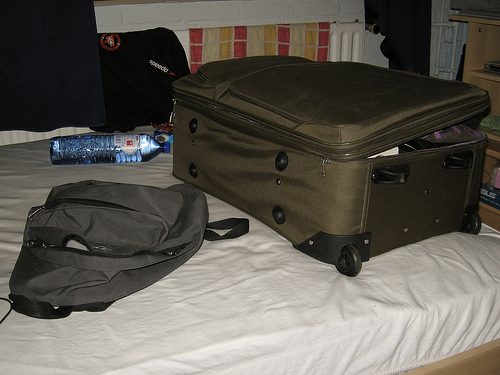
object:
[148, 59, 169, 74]
speedo brand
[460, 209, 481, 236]
wheel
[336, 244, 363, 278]
wheel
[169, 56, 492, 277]
suitcase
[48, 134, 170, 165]
bottle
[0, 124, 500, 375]
sheet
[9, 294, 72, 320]
handle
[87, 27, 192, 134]
shirt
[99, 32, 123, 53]
emblem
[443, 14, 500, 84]
shelve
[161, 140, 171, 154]
cap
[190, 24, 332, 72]
curtain